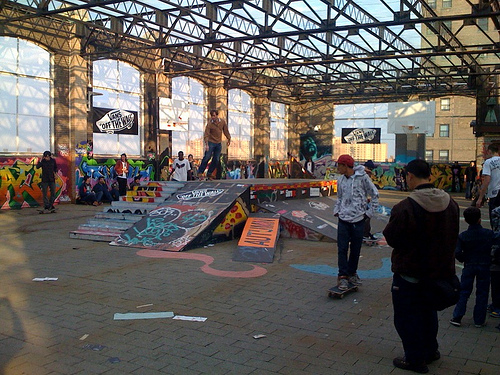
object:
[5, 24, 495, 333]
indoor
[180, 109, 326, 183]
skateboarding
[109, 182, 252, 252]
ramp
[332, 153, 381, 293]
boy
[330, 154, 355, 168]
hat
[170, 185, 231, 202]
grafitti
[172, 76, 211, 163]
windows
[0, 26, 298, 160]
row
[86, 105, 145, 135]
sign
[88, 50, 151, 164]
window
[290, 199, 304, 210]
black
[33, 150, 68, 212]
someone's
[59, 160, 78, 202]
shadow's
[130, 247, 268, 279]
shape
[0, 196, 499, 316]
floor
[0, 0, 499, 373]
warehouse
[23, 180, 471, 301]
park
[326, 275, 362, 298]
skateboard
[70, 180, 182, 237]
jumps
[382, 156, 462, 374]
spectators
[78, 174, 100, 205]
spectators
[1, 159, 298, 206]
graffiti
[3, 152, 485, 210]
walls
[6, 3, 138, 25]
metal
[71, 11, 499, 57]
rafters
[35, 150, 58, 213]
man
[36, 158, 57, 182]
coat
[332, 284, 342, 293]
grey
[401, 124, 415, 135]
basket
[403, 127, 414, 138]
net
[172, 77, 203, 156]
glass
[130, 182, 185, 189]
steps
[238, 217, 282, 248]
sign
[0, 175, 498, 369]
ground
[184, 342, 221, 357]
brick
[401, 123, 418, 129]
hoop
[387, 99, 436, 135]
backboard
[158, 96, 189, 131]
banner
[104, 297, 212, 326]
litter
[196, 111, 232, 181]
person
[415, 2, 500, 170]
building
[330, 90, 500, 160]
background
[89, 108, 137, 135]
advertisement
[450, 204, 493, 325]
child